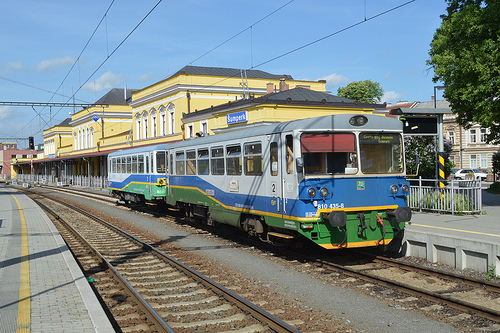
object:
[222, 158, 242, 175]
window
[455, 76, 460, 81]
leaves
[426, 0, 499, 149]
tree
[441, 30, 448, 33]
leaves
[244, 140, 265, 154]
window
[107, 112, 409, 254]
train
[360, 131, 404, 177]
window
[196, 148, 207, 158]
window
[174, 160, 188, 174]
window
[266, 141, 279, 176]
window